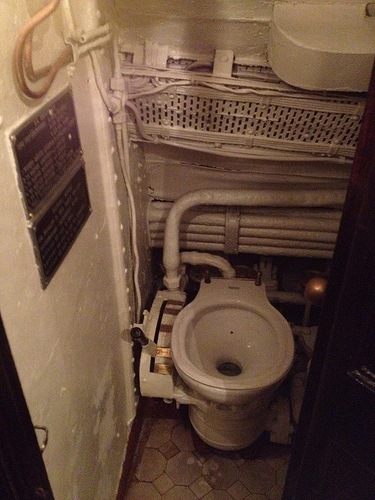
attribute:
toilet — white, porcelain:
[172, 274, 293, 436]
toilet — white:
[166, 271, 297, 460]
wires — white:
[113, 122, 144, 323]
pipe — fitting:
[113, 29, 119, 74]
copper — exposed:
[43, 22, 157, 157]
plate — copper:
[152, 346, 175, 359]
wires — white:
[94, 125, 197, 295]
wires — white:
[104, 109, 162, 229]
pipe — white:
[145, 149, 343, 292]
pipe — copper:
[7, 9, 85, 91]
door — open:
[274, 56, 370, 498]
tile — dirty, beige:
[166, 452, 200, 484]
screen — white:
[128, 79, 368, 166]